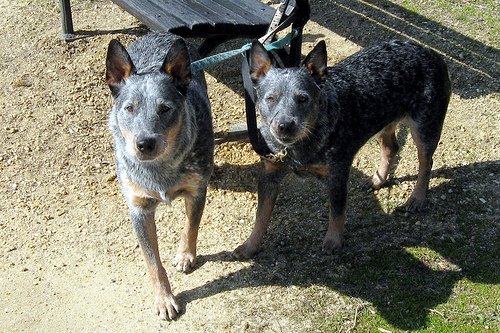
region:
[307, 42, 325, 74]
ear of the dog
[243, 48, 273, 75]
ear of the dog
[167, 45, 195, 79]
ear of the dog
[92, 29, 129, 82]
ear of the dog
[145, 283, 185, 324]
foot of the dog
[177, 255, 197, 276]
foot of the dog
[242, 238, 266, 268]
foot of the dog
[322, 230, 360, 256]
foot of the dog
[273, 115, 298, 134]
nose of the dog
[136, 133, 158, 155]
nose of the dog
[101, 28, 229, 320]
This dog is old.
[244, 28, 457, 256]
This dog is grey.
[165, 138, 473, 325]
You can see his shadow.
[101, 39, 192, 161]
His face is old.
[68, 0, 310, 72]
The bench is black.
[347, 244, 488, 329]
The grass is green.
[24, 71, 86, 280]
The dirt is brown.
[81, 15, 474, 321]
There are two dogs.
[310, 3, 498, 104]
The bench is giving a shadow,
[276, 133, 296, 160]
The dog is wearing a collar.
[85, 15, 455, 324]
Two dogs facing forward.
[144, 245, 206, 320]
The dog on the lefts paws.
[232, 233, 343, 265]
The dog on the rights paws.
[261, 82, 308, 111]
The dog on the right eyes.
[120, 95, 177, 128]
The dog on the left eyes.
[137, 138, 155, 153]
The dogs nose.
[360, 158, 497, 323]
The dogs shadow on the ground.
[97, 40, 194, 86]
The dog on the lefts ears.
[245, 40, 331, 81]
The dog on the rights ears.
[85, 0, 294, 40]
The wooden bench.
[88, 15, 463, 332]
two black dogs looking at camera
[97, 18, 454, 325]
two dogs tied to bench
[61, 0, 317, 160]
black bench behind dogs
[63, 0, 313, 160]
black metal and wood bench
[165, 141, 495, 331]
shadow of dogs on ground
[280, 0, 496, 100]
shadow of bench on ground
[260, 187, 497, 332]
grassy area in bottom right corner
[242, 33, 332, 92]
perked up dog ears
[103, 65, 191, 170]
dog face looking forward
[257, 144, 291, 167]
metal hook on dog leash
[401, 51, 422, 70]
the dog is black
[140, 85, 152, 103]
the dog is gray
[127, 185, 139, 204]
the dog is tan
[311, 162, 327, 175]
the dog is brown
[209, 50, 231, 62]
the leash is green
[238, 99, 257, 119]
the leash is black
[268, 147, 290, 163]
the clip is gold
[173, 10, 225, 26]
the bench is black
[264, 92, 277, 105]
the eye is lazy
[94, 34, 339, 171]
the dogs are blue heelers